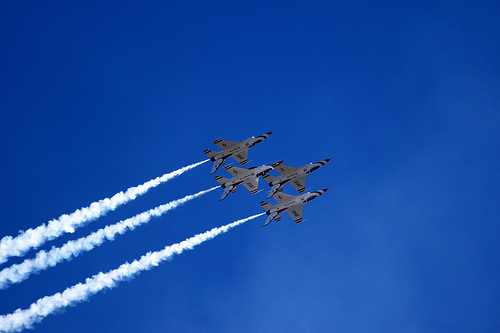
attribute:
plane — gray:
[202, 126, 282, 163]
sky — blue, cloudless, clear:
[199, 31, 241, 60]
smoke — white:
[112, 164, 142, 203]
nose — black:
[257, 124, 280, 141]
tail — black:
[197, 146, 219, 173]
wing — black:
[216, 135, 222, 145]